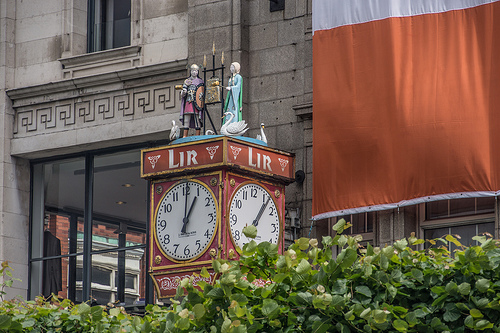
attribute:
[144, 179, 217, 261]
clock — 1, white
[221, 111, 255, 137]
swan — sculpture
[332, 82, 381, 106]
jacket — black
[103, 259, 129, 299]
window — gray, reflected, above, bronze, glass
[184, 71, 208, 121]
statue — ornate, woman, knight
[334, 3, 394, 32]
flag — orange, white, big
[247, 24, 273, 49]
building — brick, grey, stone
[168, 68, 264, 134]
glockenspiel — old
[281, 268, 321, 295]
leaves — green, bush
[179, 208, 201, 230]
hand — black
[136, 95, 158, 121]
design — diamond, here, square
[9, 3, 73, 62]
wall — brick